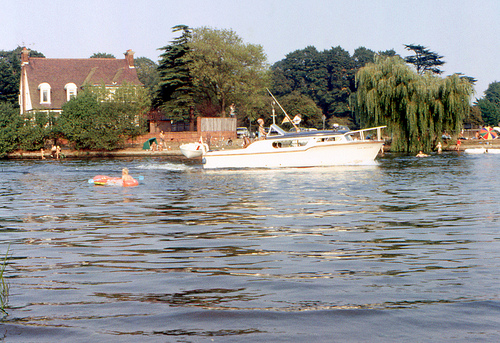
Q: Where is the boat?
A: On water.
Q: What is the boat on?
A: Water.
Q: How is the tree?
A: Bushy.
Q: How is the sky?
A: Clear.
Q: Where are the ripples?
A: In lake.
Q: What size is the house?
A: Large.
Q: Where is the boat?
A: In the water.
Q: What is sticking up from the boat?
A: A fishing pole.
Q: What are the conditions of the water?
A: Calm.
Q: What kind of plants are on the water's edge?
A: Trees.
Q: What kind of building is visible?
A: A house.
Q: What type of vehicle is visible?
A: A boat.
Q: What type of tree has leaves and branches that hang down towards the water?
A: A willow tree.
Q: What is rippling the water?
A: Waves.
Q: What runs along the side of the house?
A: A chimney.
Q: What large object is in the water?
A: A white motor boat.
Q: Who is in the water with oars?
A: Person in an inflatable boat.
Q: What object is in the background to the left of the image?
A: A house.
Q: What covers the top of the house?
A: Brown roof singles.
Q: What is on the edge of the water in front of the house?
A: A retaining wall.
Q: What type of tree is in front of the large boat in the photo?
A: A weeping willow tree.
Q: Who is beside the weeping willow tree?
A: People playing in the water.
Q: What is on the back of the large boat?
A: A small life boat.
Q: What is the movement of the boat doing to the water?
A: It is causing ripples.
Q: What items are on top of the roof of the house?
A: Two chimneys.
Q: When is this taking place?
A: Daytime.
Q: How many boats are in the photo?
A: One.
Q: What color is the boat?
A: White.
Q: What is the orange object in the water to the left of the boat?
A: Float toy.